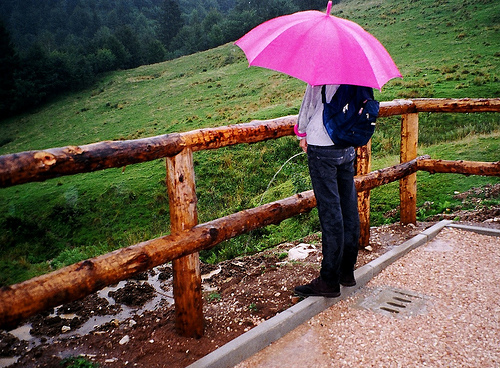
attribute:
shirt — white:
[293, 81, 357, 163]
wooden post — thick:
[395, 106, 421, 220]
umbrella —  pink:
[237, 2, 402, 139]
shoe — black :
[296, 254, 349, 307]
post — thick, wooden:
[396, 93, 453, 243]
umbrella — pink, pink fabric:
[234, 0, 408, 92]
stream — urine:
[235, 152, 301, 256]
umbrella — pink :
[236, 4, 433, 99]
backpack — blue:
[309, 72, 399, 151]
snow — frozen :
[20, 267, 193, 333]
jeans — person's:
[306, 140, 370, 295]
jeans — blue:
[302, 145, 367, 283]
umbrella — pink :
[252, 11, 385, 90]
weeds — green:
[42, 202, 78, 250]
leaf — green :
[182, 9, 193, 21]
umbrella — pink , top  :
[231, 10, 386, 97]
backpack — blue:
[322, 84, 377, 146]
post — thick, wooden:
[164, 134, 209, 339]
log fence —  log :
[3, 122, 278, 331]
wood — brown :
[172, 154, 206, 337]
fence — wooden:
[0, 90, 498, 335]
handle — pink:
[288, 122, 308, 141]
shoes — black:
[281, 250, 388, 315]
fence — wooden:
[163, 117, 290, 249]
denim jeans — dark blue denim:
[303, 145, 365, 278]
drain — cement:
[352, 287, 427, 319]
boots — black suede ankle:
[294, 255, 361, 302]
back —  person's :
[323, 84, 385, 153]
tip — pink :
[294, 135, 314, 152]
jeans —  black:
[311, 148, 362, 286]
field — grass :
[58, 67, 232, 126]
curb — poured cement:
[193, 222, 496, 367]